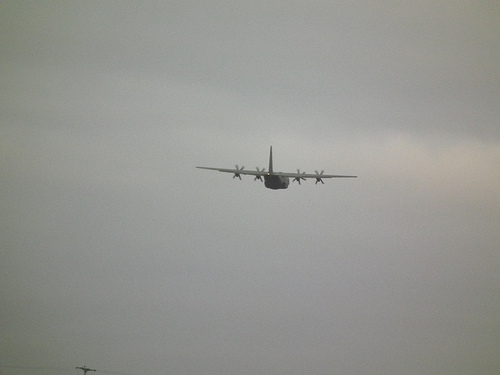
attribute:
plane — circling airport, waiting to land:
[192, 146, 367, 193]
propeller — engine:
[251, 167, 267, 182]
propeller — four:
[232, 163, 244, 181]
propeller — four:
[252, 165, 264, 182]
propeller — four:
[290, 168, 306, 185]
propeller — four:
[312, 169, 325, 184]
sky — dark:
[12, 16, 51, 74]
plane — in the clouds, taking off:
[204, 137, 361, 220]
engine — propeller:
[310, 167, 327, 185]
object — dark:
[63, 357, 105, 374]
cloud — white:
[358, 123, 498, 187]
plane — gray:
[196, 145, 361, 196]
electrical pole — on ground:
[75, 365, 97, 373]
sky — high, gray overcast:
[1, 2, 496, 370]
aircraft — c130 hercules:
[196, 144, 358, 193]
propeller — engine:
[292, 167, 308, 186]